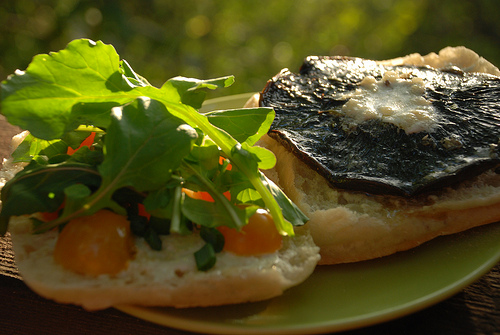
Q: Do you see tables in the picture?
A: Yes, there is a table.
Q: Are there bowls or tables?
A: Yes, there is a table.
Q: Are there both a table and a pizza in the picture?
A: No, there is a table but no pizzas.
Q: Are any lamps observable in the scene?
A: No, there are no lamps.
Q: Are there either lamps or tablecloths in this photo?
A: No, there are no lamps or tablecloths.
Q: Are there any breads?
A: Yes, there is a bread.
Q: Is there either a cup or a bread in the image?
A: Yes, there is a bread.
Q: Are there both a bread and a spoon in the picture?
A: No, there is a bread but no spoons.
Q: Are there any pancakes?
A: No, there are no pancakes.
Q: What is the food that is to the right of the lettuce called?
A: The food is a bread.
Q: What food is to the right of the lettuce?
A: The food is a bread.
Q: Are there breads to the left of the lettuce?
A: No, the bread is to the right of the lettuce.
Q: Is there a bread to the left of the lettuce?
A: No, the bread is to the right of the lettuce.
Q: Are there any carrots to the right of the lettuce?
A: No, there is a bread to the right of the lettuce.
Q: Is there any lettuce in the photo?
A: Yes, there is lettuce.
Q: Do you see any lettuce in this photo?
A: Yes, there is lettuce.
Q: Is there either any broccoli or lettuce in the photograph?
A: Yes, there is lettuce.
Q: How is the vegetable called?
A: The vegetable is lettuce.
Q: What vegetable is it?
A: The vegetable is lettuce.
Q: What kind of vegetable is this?
A: This is lettuce.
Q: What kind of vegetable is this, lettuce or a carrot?
A: This is lettuce.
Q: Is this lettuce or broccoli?
A: This is lettuce.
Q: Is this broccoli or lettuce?
A: This is lettuce.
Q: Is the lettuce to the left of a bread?
A: Yes, the lettuce is to the left of a bread.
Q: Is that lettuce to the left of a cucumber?
A: No, the lettuce is to the left of a bread.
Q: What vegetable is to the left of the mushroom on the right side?
A: The vegetable is lettuce.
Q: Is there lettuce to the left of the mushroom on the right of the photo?
A: Yes, there is lettuce to the left of the mushroom.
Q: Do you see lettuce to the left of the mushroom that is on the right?
A: Yes, there is lettuce to the left of the mushroom.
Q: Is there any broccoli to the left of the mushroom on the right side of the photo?
A: No, there is lettuce to the left of the mushroom.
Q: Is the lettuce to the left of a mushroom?
A: Yes, the lettuce is to the left of a mushroom.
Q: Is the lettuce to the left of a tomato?
A: No, the lettuce is to the left of a mushroom.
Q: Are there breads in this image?
A: Yes, there is a bread.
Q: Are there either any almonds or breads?
A: Yes, there is a bread.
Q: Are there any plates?
A: Yes, there is a plate.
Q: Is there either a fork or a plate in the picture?
A: Yes, there is a plate.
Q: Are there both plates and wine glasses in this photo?
A: No, there is a plate but no wine glasses.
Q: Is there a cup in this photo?
A: No, there are no cups.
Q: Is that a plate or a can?
A: That is a plate.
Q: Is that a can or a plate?
A: That is a plate.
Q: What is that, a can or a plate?
A: That is a plate.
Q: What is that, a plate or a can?
A: That is a plate.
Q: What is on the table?
A: The plate is on the table.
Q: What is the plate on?
A: The plate is on the table.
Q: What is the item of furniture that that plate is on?
A: The piece of furniture is a table.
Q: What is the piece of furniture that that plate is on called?
A: The piece of furniture is a table.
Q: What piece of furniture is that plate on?
A: The plate is on the table.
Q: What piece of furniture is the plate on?
A: The plate is on the table.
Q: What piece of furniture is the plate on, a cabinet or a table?
A: The plate is on a table.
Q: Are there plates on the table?
A: Yes, there is a plate on the table.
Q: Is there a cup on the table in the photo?
A: No, there is a plate on the table.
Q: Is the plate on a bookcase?
A: No, the plate is on the table.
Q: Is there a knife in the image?
A: No, there are no knives.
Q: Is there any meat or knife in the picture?
A: No, there are no knives or meat.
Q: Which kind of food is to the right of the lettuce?
A: The food is a mushroom.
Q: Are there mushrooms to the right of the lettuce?
A: Yes, there is a mushroom to the right of the lettuce.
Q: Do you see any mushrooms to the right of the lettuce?
A: Yes, there is a mushroom to the right of the lettuce.